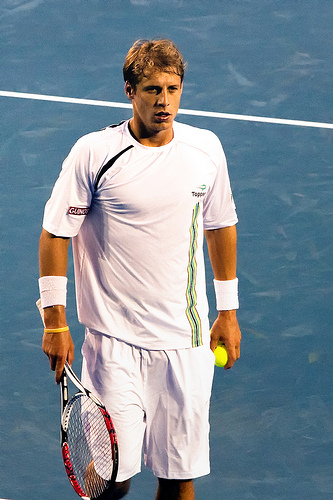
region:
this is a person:
[40, 25, 245, 498]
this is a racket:
[31, 343, 131, 498]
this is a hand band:
[23, 272, 75, 316]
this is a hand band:
[209, 274, 248, 315]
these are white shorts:
[81, 322, 221, 487]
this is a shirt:
[31, 116, 234, 355]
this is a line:
[211, 86, 268, 144]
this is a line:
[32, 84, 79, 132]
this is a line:
[272, 117, 312, 140]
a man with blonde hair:
[111, 44, 195, 134]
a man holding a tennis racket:
[26, 285, 120, 489]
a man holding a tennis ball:
[191, 305, 253, 378]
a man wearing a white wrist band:
[196, 269, 251, 333]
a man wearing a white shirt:
[45, 132, 235, 291]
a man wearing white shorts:
[45, 341, 224, 488]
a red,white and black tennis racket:
[30, 381, 125, 498]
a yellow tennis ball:
[199, 330, 243, 377]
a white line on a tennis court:
[188, 103, 325, 131]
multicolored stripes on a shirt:
[176, 186, 208, 385]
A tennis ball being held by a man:
[211, 342, 229, 367]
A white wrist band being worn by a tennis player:
[212, 277, 240, 311]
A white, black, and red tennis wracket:
[58, 359, 119, 498]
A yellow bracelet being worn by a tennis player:
[43, 327, 68, 333]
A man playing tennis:
[37, 36, 242, 496]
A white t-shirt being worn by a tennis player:
[40, 117, 239, 349]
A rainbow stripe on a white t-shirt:
[185, 201, 204, 347]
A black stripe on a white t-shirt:
[93, 144, 133, 192]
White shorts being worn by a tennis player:
[79, 325, 214, 482]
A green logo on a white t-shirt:
[195, 182, 206, 190]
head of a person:
[112, 42, 200, 144]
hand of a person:
[208, 311, 257, 365]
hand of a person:
[35, 326, 83, 375]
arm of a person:
[30, 190, 87, 302]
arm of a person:
[194, 169, 260, 298]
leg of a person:
[52, 414, 127, 498]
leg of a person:
[135, 415, 203, 489]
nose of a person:
[158, 89, 176, 107]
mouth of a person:
[150, 111, 180, 125]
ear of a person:
[121, 72, 143, 112]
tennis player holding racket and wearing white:
[33, 33, 241, 490]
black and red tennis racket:
[30, 294, 136, 498]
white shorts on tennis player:
[77, 327, 238, 476]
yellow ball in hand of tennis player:
[209, 341, 235, 372]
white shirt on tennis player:
[41, 117, 240, 352]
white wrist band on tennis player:
[32, 272, 70, 310]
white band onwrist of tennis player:
[209, 275, 240, 312]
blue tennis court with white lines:
[2, 2, 332, 496]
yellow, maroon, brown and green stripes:
[186, 201, 205, 348]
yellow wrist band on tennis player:
[40, 324, 70, 337]